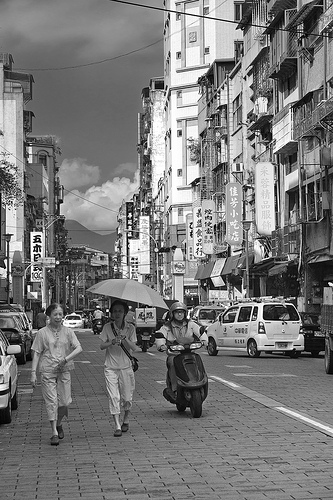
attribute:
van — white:
[217, 305, 289, 355]